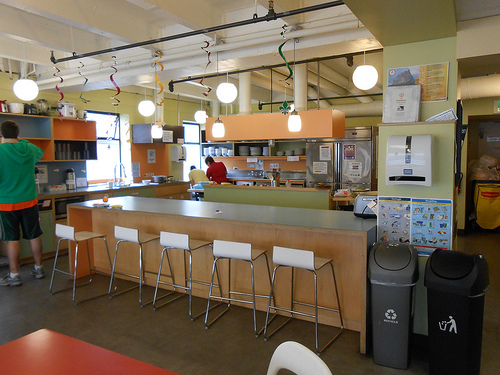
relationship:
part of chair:
[257, 330, 320, 375] [266, 336, 337, 372]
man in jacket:
[4, 137, 42, 203] [13, 150, 18, 164]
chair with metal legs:
[266, 336, 337, 372] [267, 264, 338, 335]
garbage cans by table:
[378, 236, 478, 351] [10, 349, 82, 359]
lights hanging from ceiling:
[106, 78, 390, 129] [104, 14, 151, 21]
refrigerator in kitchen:
[358, 142, 365, 155] [94, 107, 361, 221]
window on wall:
[82, 102, 134, 185] [128, 95, 148, 100]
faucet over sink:
[111, 159, 135, 177] [99, 185, 144, 195]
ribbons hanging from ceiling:
[53, 36, 314, 83] [104, 14, 151, 21]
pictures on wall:
[387, 199, 450, 251] [128, 95, 148, 100]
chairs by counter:
[62, 220, 337, 328] [89, 189, 377, 246]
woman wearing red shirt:
[198, 148, 240, 194] [205, 165, 238, 180]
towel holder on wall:
[419, 141, 426, 145] [128, 95, 148, 100]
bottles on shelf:
[52, 142, 96, 158] [55, 117, 105, 165]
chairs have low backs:
[62, 220, 337, 328] [272, 249, 329, 266]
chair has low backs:
[163, 229, 208, 247] [272, 249, 329, 266]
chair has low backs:
[266, 336, 337, 372] [272, 249, 329, 266]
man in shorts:
[4, 137, 42, 203] [5, 205, 54, 245]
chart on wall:
[387, 199, 450, 251] [128, 95, 148, 100]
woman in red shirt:
[198, 148, 240, 194] [205, 165, 238, 180]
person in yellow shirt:
[179, 165, 202, 169] [193, 167, 201, 186]